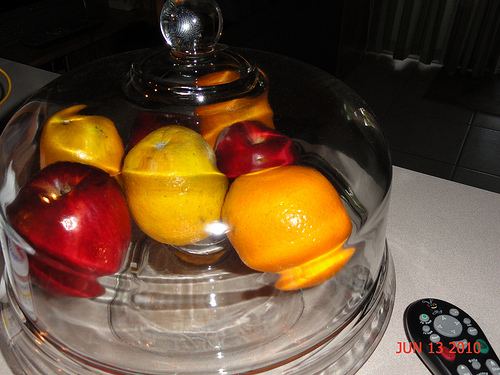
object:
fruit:
[220, 165, 352, 272]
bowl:
[4, 0, 397, 374]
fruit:
[5, 161, 132, 274]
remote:
[402, 297, 499, 374]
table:
[396, 186, 498, 298]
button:
[433, 315, 463, 338]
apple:
[215, 120, 296, 178]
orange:
[121, 125, 228, 246]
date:
[396, 342, 482, 354]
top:
[159, 0, 223, 54]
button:
[476, 338, 489, 353]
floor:
[0, 0, 500, 195]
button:
[439, 346, 456, 361]